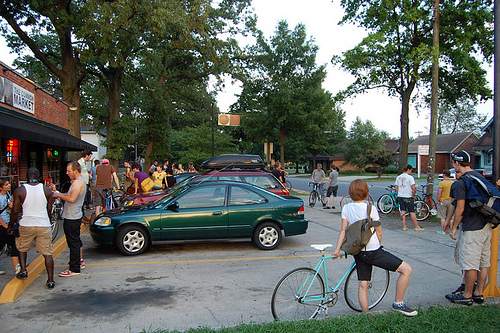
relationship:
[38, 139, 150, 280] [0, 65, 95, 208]
people outside market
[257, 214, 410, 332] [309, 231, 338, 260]
bike has seat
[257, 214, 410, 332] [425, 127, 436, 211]
bike by pole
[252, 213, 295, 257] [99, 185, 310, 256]
tire of car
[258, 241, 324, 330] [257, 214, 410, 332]
tire of bike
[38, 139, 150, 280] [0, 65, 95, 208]
people by market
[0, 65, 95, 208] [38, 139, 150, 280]
market for people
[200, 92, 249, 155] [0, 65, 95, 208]
sign for market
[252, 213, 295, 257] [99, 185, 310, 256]
tire on car